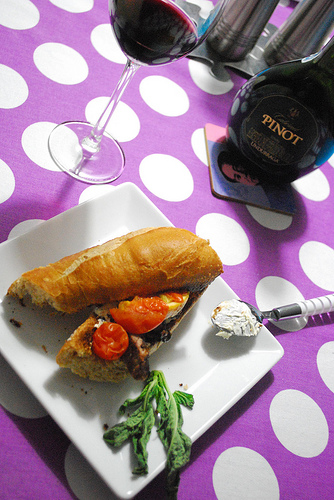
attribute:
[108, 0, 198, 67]
wine — dark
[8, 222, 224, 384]
sandwich — toasted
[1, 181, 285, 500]
plate — white, square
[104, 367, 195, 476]
garnish — limp, green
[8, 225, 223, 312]
loaf — crusty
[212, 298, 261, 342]
condiment — white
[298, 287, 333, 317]
handle — white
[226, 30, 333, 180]
wine bottle — curved, dark, glass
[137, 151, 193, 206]
dot — white, large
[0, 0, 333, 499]
tablecloth — purple, white, polka dot, spotted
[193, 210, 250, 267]
dot — white, large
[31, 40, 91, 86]
dot — white, large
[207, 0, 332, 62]
containers — metal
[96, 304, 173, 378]
meats — roasted